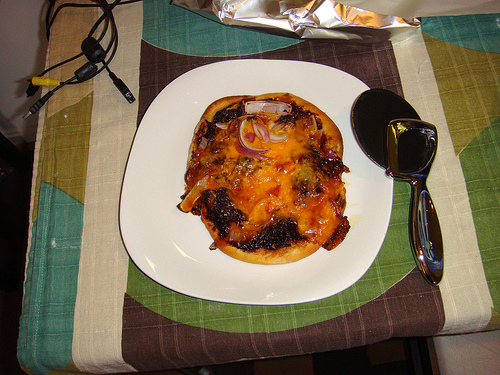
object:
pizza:
[177, 92, 352, 267]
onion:
[235, 114, 267, 161]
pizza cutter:
[349, 83, 445, 288]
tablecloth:
[61, 64, 499, 373]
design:
[43, 166, 133, 313]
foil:
[233, 5, 418, 43]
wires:
[49, 15, 119, 97]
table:
[20, 0, 496, 373]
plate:
[115, 57, 395, 307]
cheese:
[230, 142, 287, 219]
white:
[93, 100, 109, 224]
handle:
[407, 175, 448, 288]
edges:
[113, 69, 210, 146]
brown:
[140, 47, 157, 89]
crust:
[291, 203, 348, 259]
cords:
[38, 21, 110, 76]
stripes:
[261, 23, 485, 66]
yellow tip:
[20, 73, 65, 88]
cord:
[31, 46, 120, 89]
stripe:
[392, 20, 494, 304]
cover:
[31, 76, 61, 87]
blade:
[342, 89, 426, 179]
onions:
[242, 100, 292, 115]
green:
[238, 305, 291, 334]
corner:
[11, 289, 86, 372]